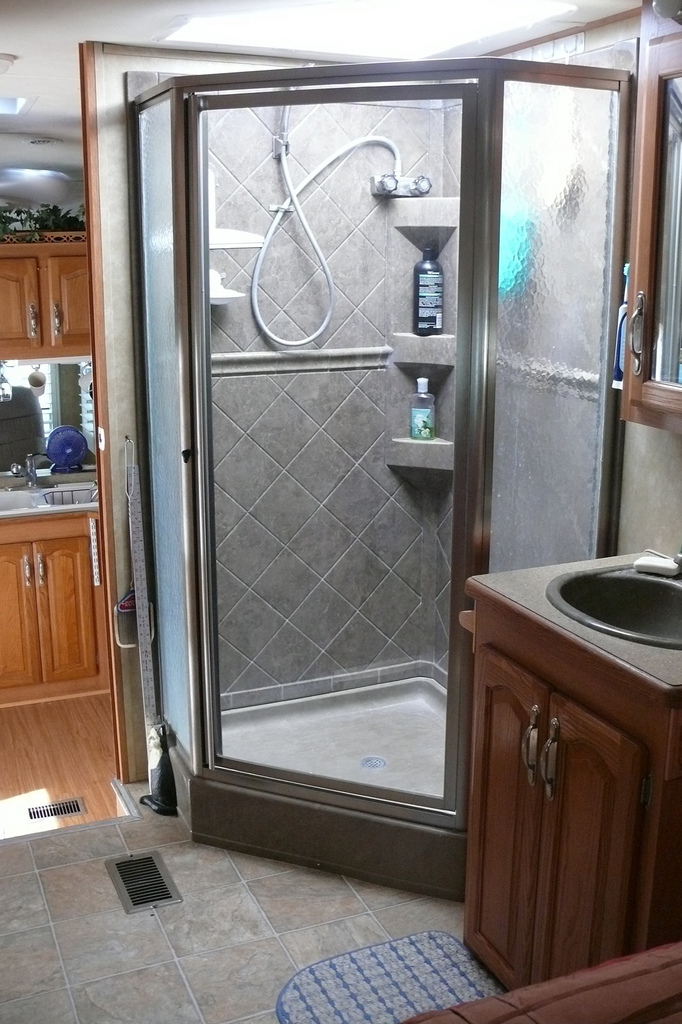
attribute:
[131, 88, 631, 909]
shower stall — empty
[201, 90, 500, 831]
bathroom — silver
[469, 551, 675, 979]
bathroom — brown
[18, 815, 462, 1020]
tile — gray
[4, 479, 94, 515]
sink — white, kitchen sink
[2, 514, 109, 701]
cabinets — brown, kitchen cabinets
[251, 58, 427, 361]
shower head — one held 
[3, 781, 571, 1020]
floor — brown, hardwood floor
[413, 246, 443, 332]
bottle — white, plastic bottle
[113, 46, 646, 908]
shower — white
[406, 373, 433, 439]
bottle — plastic bottle, clear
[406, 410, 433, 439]
label — blue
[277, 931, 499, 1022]
rug — blue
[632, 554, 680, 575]
soap — white bar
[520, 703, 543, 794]
handle — bronze door handle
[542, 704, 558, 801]
handle — bronze door handle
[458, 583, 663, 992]
cabinet — wood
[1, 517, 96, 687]
cabinet — wood cabinet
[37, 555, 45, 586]
handle — bronze door handle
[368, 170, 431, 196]
knobs — water control knobs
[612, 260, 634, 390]
toothbrush — electric, blue , white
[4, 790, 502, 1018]
floor — green, tiled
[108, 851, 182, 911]
vent — silver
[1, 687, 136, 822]
floor — wood floor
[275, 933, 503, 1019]
mat — bath mat, in front 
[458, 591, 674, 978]
base — wooden base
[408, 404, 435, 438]
label — blue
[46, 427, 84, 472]
fan — blue, above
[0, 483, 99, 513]
sink — kitchen sink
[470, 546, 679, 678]
sink — bathroom sink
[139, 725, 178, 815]
decoration — cat decoration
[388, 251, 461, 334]
bottle — black